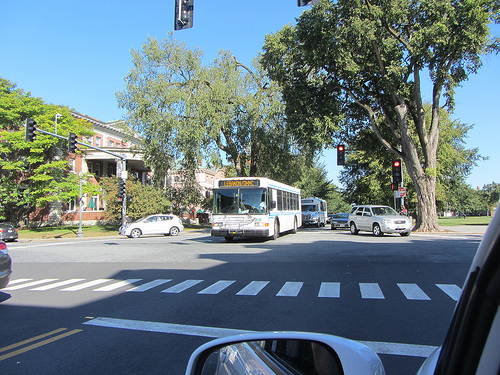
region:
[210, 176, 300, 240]
a white and blue bus driving down the street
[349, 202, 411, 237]
a grey SUV taking a turn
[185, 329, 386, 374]
a white car mirror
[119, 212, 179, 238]
a white car taking a tirn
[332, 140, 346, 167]
a traffic light hanging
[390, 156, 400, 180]
a traffic light hanging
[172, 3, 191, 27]
a traffic light hanging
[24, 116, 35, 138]
a traffic light hanging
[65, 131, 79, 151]
a traffic light hanging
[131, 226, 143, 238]
a black wheel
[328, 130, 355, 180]
a red light on a traffic light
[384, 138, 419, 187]
a red light on a traffic light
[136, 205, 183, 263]
a white station wagon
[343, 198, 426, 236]
a silver SUV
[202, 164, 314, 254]
a city bus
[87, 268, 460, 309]
lines painted in the street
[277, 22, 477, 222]
a tall leafy tree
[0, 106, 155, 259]
a red and white house on the corner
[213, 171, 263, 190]
the destination of the bus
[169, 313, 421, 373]
a side mirror on a white car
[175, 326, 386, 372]
Driver's Left Rear View Mirror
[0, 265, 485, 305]
White Marks Indicate Crosswalk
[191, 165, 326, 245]
1 Bus Following Another Bus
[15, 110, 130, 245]
3 Traffic Lights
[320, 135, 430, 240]
2 Traffic Lights Showing Red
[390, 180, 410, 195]
Do Not Enter Sign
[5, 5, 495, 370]
Beautiful Summer Day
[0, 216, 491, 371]
Road is in Very Good Condition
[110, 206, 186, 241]
Little White Car Getting Ready to Turn Right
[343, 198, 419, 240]
Car Getting Ready to Turn Left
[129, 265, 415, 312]
There are white rectangles on the pavement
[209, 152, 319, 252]
The bus is on its way to a destination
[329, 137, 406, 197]
The traffic lights are red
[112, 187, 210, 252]
The car is turning right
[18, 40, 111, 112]
The sky is blue with no clouds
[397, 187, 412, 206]
A do not enter sign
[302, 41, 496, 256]
A tall tree beside the road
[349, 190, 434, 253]
A car is turning left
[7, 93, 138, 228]
A pole with traffic lights on it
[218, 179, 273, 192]
The destination of the bus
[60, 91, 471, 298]
vehicles driving on the road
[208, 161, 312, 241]
bus driving on road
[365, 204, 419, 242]
silver car driving by tree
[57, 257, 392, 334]
white marks on street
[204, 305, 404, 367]
side view mirror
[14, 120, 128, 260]
red brick building by street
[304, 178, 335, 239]
bus behind other bus on street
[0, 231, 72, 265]
rear tail light of car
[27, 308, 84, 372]
yellow lines on street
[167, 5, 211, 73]
stop light above street